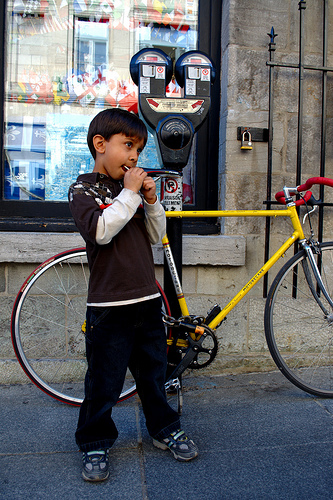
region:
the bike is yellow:
[87, 170, 328, 407]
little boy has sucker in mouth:
[99, 135, 167, 203]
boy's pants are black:
[67, 290, 181, 418]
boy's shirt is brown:
[68, 169, 158, 282]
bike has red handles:
[253, 146, 331, 216]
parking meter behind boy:
[113, 28, 239, 222]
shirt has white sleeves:
[92, 173, 156, 245]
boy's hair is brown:
[63, 88, 182, 161]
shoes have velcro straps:
[55, 397, 209, 472]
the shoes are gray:
[49, 413, 226, 469]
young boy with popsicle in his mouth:
[67, 107, 159, 199]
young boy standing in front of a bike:
[10, 109, 324, 484]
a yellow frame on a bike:
[143, 196, 329, 357]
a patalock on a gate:
[233, 17, 321, 310]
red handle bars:
[268, 175, 331, 204]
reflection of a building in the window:
[5, 2, 201, 208]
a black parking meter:
[128, 43, 215, 394]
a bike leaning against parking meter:
[9, 49, 328, 411]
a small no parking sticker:
[162, 177, 179, 196]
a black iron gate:
[247, 6, 331, 299]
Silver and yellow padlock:
[238, 128, 257, 152]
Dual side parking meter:
[129, 44, 220, 369]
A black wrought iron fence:
[249, 12, 332, 302]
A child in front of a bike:
[13, 98, 331, 433]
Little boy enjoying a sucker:
[49, 100, 202, 482]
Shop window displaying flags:
[3, 3, 209, 119]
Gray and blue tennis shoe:
[135, 415, 204, 466]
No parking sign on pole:
[157, 169, 186, 216]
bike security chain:
[162, 306, 227, 330]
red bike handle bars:
[258, 166, 331, 213]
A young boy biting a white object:
[70, 106, 199, 482]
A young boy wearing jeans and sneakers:
[69, 106, 199, 481]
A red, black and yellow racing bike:
[10, 168, 332, 407]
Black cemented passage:
[0, 365, 331, 498]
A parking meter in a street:
[131, 48, 217, 392]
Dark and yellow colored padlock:
[237, 126, 270, 151]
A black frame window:
[1, 0, 221, 231]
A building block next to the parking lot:
[0, 0, 332, 387]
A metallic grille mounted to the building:
[266, 0, 332, 298]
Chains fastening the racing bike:
[162, 305, 213, 330]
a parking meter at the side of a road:
[130, 43, 225, 142]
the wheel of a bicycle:
[264, 237, 329, 397]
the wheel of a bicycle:
[9, 243, 82, 410]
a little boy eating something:
[86, 108, 170, 203]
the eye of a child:
[120, 135, 140, 153]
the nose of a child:
[127, 147, 139, 164]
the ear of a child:
[89, 130, 107, 155]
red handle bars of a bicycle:
[267, 171, 332, 200]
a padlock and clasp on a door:
[231, 122, 276, 153]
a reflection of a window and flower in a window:
[36, 2, 114, 109]